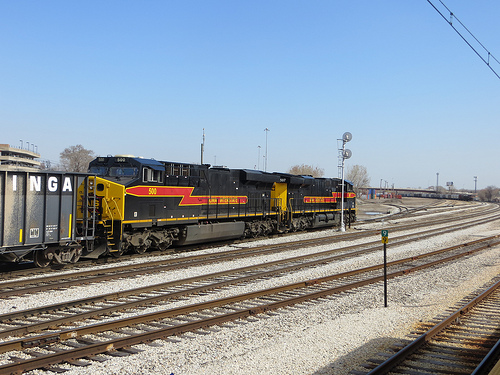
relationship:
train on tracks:
[1, 142, 356, 270] [3, 196, 500, 372]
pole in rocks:
[381, 244, 391, 309] [365, 285, 413, 314]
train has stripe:
[1, 142, 356, 270] [129, 182, 253, 209]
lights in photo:
[91, 157, 136, 164] [4, 4, 498, 373]